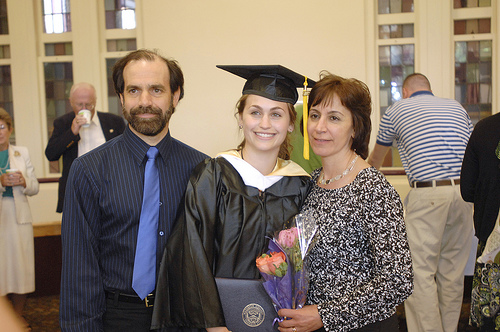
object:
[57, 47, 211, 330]
man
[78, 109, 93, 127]
cup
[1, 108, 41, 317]
woman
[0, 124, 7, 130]
glasses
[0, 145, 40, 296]
white dress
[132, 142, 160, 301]
tie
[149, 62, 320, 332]
woman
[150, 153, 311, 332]
graduation gown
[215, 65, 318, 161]
cap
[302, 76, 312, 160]
yellow tassles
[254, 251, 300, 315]
roses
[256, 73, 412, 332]
woman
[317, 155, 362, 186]
necklace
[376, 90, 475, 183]
shirt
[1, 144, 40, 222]
coat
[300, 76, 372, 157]
hair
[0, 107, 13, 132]
hair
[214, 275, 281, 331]
graduation document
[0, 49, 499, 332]
people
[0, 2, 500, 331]
building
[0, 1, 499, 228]
wall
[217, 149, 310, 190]
white collar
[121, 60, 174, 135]
man's face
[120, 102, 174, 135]
beard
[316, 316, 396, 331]
brown pants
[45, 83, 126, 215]
man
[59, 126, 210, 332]
shirt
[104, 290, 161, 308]
belt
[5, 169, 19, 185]
cup